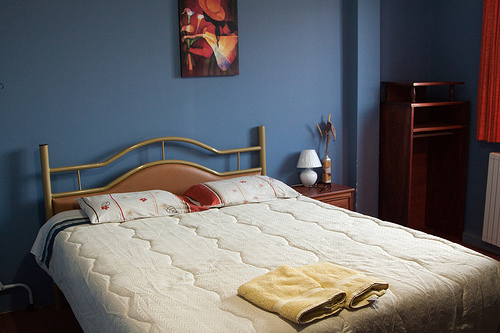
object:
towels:
[237, 265, 346, 326]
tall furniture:
[380, 80, 466, 240]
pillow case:
[183, 175, 302, 209]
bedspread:
[29, 206, 500, 332]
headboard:
[38, 125, 266, 218]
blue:
[273, 43, 319, 97]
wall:
[381, 0, 445, 85]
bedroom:
[0, 0, 499, 333]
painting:
[176, 0, 239, 78]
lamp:
[296, 149, 322, 187]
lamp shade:
[296, 149, 323, 169]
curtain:
[474, 0, 499, 142]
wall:
[445, 1, 498, 258]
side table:
[291, 183, 355, 211]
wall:
[0, 0, 344, 279]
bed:
[29, 124, 500, 333]